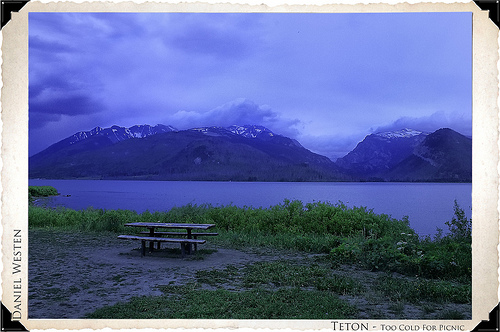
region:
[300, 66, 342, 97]
white clouds in blue sky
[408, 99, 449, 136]
white clouds in blue sky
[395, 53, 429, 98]
white clouds in blue sky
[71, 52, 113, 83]
white clouds in blue sky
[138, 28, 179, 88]
white clouds in blue skywhite clouds in blue sky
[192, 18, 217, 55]
white clouds in blue sky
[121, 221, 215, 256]
A wooden bench on the ground.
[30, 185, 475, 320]
Grass lines up the shore.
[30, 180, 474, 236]
A lake is blue.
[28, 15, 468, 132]
Huge fluffy clouds in the sky.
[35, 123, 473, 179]
A mountain can be seen in the distance.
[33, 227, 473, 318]
Patches of earth are in the ground.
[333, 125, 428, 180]
Snow on the top of the mountain.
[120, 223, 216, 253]
The bench looks old.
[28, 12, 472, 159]
The sky looks dark.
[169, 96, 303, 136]
The cloud looks like it's about to rain.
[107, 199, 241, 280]
wooden table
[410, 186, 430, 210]
ripples in clear and blue water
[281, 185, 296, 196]
ripples in clear and blue water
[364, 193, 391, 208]
ripples in clear and blue water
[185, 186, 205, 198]
ripples in clear and blue water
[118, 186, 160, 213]
ripples in clear and blue water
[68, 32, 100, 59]
white clouds in blue sky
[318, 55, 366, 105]
white clouds in blue sky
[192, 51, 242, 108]
white clouds in blue sky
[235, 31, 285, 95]
white clouds in blue sky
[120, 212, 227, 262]
wooden bench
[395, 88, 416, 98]
white clouds in blue sky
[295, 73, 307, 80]
white clouds in blue sky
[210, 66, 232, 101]
white clouds in blue sky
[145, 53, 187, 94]
white clouds in blue sky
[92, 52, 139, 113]
white clouds in blue sky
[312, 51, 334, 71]
white clouds in blue sky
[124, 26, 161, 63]
white clouds in blue sky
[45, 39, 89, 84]
white clouds in blue sky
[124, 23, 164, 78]
white clouds in blue sky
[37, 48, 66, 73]
white clouds in blue sky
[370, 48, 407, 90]
white clouds in blue sky